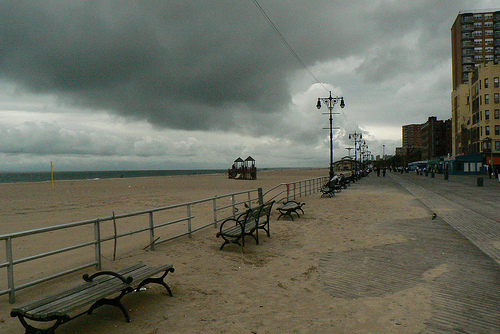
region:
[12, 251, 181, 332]
bench in the sand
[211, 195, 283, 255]
bench in the sand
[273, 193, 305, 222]
bench in the sand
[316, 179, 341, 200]
bench in the sand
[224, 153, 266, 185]
two small huts in the sand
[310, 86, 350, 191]
street light on the beach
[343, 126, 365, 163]
street light on the beach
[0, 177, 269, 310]
silver metal fence on the beach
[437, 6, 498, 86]
tall brown building on the beach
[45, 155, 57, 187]
yellow pole in the ground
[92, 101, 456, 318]
benches on the beach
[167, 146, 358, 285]
beach on the sand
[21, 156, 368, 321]
benches in front of a fence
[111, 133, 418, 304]
benches in front of a metal fence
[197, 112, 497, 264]
beach against a sidewalk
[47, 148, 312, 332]
a beach covered in sand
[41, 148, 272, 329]
a sand covered beach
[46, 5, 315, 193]
skies with white clouds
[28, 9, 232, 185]
skies full of clouds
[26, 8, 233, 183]
clouds in the sky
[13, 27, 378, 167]
the sky is overcast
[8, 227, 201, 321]
the bench does not have a back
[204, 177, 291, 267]
the bench is empty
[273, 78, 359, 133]
the lights are off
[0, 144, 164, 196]
the water is greenish blue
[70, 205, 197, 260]
the fence is broken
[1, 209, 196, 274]
the fence is grey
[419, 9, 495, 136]
the building is tall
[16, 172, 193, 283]
the sand is wet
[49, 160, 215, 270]
the sand is beige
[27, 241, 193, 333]
bench does not have a back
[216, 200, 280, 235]
bench has a back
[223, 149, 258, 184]
play set on the bench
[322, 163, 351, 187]
people sitting on the bench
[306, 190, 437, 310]
sand on the boardwalk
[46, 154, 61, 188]
yellow pole on the beach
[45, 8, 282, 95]
dark thick clouds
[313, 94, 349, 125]
two lights on a light pole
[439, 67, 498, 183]
building is mustard yellow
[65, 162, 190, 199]
no one on the beach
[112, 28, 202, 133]
the clouds are black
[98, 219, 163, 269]
the gate is broken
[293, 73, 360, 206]
streetlight in the sand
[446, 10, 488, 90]
high rise on broadwalk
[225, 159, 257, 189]
playground in the sand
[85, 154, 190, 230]
ocean to the left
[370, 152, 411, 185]
people are walking away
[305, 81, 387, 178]
streetlights are present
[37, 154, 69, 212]
yellow pole in the sand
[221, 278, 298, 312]
footprints are in the sand